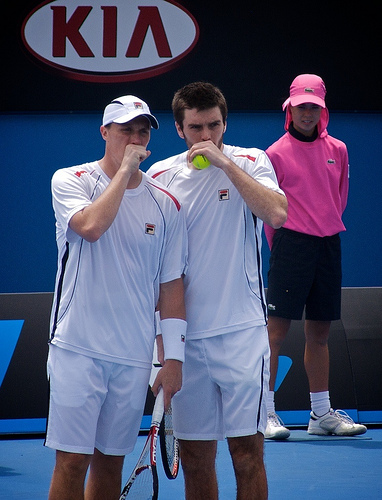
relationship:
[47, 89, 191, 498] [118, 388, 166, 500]
man holding tennis racket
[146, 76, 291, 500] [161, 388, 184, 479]
man holding tennis racket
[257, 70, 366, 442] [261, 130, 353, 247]
person wearing a shirt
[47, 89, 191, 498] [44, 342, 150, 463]
man wearing shorts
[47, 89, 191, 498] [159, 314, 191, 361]
man wearing a wristband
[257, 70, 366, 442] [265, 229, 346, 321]
person wearing shorts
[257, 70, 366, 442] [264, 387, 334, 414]
person wearing socks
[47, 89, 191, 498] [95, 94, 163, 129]
man wearing a hat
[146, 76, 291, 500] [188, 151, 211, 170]
man holding ball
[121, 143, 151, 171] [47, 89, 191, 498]
hand in front of man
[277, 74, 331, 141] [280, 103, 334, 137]
hat has flaps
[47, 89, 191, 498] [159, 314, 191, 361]
man has a wristband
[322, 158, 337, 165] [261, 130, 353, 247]
logo on shirt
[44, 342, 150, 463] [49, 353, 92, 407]
shorts have a pocket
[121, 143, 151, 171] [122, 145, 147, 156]
hand lifted to mouth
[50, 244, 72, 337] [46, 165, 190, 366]
stripe on side of shirt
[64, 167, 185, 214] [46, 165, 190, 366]
stripes are on shoulder of shirt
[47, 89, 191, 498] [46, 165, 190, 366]
man wearing a shirt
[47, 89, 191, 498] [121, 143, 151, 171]
man has a hand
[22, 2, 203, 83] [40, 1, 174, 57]
logo says kia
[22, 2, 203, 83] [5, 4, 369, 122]
logo in background